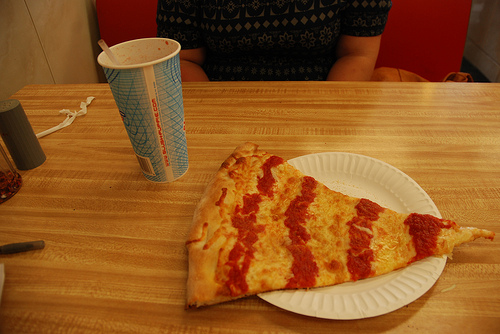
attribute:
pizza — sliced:
[178, 130, 496, 324]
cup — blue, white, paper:
[97, 38, 188, 180]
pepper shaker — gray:
[0, 100, 45, 169]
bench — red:
[97, 1, 473, 77]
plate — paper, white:
[260, 153, 445, 322]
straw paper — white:
[36, 98, 94, 137]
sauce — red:
[405, 214, 444, 254]